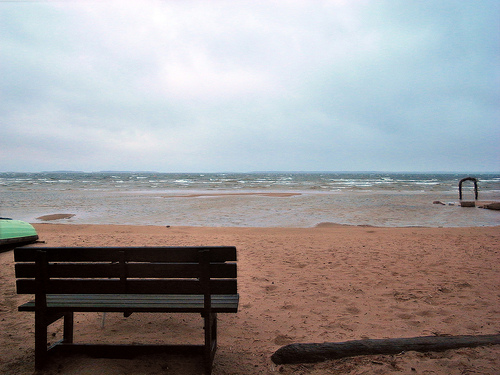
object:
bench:
[12, 245, 239, 375]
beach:
[0, 220, 500, 375]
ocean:
[0, 169, 500, 197]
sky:
[1, 0, 499, 175]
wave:
[314, 175, 448, 188]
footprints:
[232, 238, 496, 374]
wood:
[269, 333, 499, 366]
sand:
[0, 223, 499, 373]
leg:
[202, 308, 213, 374]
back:
[10, 245, 241, 315]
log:
[269, 333, 499, 366]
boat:
[0, 219, 38, 246]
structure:
[457, 177, 480, 201]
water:
[0, 181, 500, 229]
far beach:
[0, 184, 499, 228]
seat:
[15, 291, 238, 312]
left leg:
[33, 309, 47, 372]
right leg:
[210, 309, 218, 351]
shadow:
[29, 339, 210, 375]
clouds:
[0, 0, 499, 176]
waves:
[4, 171, 499, 189]